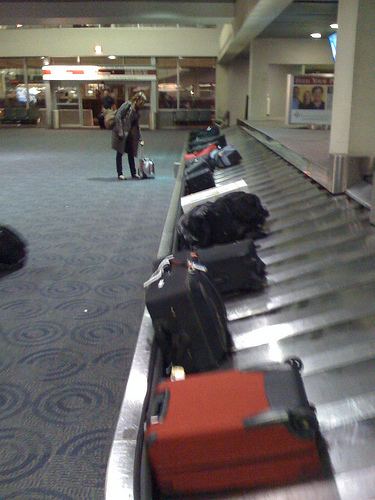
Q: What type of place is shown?
A: It is an airport.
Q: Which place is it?
A: It is an airport.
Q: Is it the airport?
A: Yes, it is the airport.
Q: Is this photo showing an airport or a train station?
A: It is showing an airport.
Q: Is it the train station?
A: No, it is the airport.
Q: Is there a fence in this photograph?
A: No, there are no fences.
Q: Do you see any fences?
A: No, there are no fences.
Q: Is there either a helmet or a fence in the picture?
A: No, there are no fences or helmets.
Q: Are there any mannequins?
A: No, there are no mannequins.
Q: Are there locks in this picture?
A: No, there are no locks.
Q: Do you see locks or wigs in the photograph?
A: No, there are no locks or wigs.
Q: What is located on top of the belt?
A: The luggage is on top of the belt.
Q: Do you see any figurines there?
A: No, there are no figurines.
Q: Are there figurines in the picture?
A: No, there are no figurines.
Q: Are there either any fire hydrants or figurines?
A: No, there are no figurines or fire hydrants.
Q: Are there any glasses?
A: No, there are no glasses.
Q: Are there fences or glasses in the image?
A: No, there are no glasses or fences.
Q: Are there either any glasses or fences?
A: No, there are no glasses or fences.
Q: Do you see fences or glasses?
A: No, there are no glasses or fences.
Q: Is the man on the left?
A: Yes, the man is on the left of the image.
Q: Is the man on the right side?
A: No, the man is on the left of the image.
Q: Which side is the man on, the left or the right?
A: The man is on the left of the image.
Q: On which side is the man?
A: The man is on the left of the image.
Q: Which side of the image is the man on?
A: The man is on the left of the image.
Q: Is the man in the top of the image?
A: Yes, the man is in the top of the image.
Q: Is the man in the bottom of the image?
A: No, the man is in the top of the image.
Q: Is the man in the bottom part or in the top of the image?
A: The man is in the top of the image.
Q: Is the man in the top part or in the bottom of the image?
A: The man is in the top of the image.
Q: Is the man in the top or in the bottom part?
A: The man is in the top of the image.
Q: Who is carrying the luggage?
A: The man is carrying the luggage.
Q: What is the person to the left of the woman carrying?
A: The man is carrying luggage.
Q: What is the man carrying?
A: The man is carrying luggage.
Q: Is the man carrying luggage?
A: Yes, the man is carrying luggage.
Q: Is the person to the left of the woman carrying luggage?
A: Yes, the man is carrying luggage.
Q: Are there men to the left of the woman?
A: Yes, there is a man to the left of the woman.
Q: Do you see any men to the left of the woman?
A: Yes, there is a man to the left of the woman.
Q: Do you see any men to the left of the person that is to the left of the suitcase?
A: Yes, there is a man to the left of the woman.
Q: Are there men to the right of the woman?
A: No, the man is to the left of the woman.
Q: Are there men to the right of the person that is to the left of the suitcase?
A: No, the man is to the left of the woman.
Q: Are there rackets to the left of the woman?
A: No, there is a man to the left of the woman.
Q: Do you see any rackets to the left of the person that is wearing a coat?
A: No, there is a man to the left of the woman.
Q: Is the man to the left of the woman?
A: Yes, the man is to the left of the woman.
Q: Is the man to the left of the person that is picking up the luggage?
A: Yes, the man is to the left of the woman.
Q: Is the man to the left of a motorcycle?
A: No, the man is to the left of the woman.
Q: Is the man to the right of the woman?
A: No, the man is to the left of the woman.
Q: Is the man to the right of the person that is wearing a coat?
A: No, the man is to the left of the woman.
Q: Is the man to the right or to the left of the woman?
A: The man is to the left of the woman.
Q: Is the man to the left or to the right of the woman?
A: The man is to the left of the woman.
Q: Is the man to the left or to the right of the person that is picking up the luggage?
A: The man is to the left of the woman.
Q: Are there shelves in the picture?
A: No, there are no shelves.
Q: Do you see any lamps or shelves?
A: No, there are no shelves or lamps.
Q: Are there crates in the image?
A: No, there are no crates.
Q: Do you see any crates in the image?
A: No, there are no crates.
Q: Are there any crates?
A: No, there are no crates.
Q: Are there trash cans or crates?
A: No, there are no crates or trash cans.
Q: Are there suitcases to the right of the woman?
A: Yes, there is a suitcase to the right of the woman.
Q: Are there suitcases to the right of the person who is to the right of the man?
A: Yes, there is a suitcase to the right of the woman.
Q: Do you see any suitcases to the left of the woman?
A: No, the suitcase is to the right of the woman.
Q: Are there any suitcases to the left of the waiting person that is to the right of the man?
A: No, the suitcase is to the right of the woman.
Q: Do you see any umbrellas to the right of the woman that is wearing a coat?
A: No, there is a suitcase to the right of the woman.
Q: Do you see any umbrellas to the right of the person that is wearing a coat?
A: No, there is a suitcase to the right of the woman.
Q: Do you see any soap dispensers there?
A: No, there are no soap dispensers.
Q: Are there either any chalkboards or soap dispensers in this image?
A: No, there are no soap dispensers or chalkboards.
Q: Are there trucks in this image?
A: No, there are no trucks.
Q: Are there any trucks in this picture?
A: No, there are no trucks.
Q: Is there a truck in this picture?
A: No, there are no trucks.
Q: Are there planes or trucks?
A: No, there are no trucks or planes.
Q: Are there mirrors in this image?
A: No, there are no mirrors.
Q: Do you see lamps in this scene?
A: No, there are no lamps.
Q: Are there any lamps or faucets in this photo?
A: No, there are no lamps or faucets.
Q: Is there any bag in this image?
A: Yes, there is a bag.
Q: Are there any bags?
A: Yes, there is a bag.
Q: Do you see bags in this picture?
A: Yes, there is a bag.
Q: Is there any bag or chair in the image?
A: Yes, there is a bag.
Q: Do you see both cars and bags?
A: No, there is a bag but no cars.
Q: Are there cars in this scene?
A: No, there are no cars.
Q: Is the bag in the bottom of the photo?
A: Yes, the bag is in the bottom of the image.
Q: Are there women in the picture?
A: Yes, there is a woman.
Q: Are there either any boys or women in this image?
A: Yes, there is a woman.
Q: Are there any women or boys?
A: Yes, there is a woman.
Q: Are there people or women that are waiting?
A: Yes, the woman is waiting.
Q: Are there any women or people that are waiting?
A: Yes, the woman is waiting.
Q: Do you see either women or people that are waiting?
A: Yes, the woman is waiting.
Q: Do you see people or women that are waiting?
A: Yes, the woman is waiting.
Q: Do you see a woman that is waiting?
A: Yes, there is a woman that is waiting.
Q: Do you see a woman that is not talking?
A: Yes, there is a woman that is waiting .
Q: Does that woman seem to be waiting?
A: Yes, the woman is waiting.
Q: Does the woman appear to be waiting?
A: Yes, the woman is waiting.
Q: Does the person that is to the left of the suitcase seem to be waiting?
A: Yes, the woman is waiting.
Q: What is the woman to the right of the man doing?
A: The woman is waiting.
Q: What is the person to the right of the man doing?
A: The woman is waiting.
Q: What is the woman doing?
A: The woman is waiting.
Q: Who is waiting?
A: The woman is waiting.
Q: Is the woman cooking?
A: No, the woman is waiting.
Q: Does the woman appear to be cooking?
A: No, the woman is waiting.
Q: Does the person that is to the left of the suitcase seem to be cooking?
A: No, the woman is waiting.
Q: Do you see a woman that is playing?
A: No, there is a woman but she is waiting.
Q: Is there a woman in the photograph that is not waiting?
A: No, there is a woman but she is waiting.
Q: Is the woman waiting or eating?
A: The woman is waiting.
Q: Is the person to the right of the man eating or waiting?
A: The woman is waiting.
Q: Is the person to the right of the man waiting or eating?
A: The woman is waiting.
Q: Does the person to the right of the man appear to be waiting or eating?
A: The woman is waiting.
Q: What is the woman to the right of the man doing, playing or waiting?
A: The woman is waiting.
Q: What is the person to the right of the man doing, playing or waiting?
A: The woman is waiting.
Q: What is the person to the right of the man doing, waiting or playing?
A: The woman is waiting.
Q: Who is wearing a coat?
A: The woman is wearing a coat.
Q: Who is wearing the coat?
A: The woman is wearing a coat.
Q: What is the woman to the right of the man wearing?
A: The woman is wearing a coat.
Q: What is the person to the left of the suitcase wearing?
A: The woman is wearing a coat.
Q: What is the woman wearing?
A: The woman is wearing a coat.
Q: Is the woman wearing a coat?
A: Yes, the woman is wearing a coat.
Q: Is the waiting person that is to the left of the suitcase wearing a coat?
A: Yes, the woman is wearing a coat.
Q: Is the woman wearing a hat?
A: No, the woman is wearing a coat.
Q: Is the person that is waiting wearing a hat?
A: No, the woman is wearing a coat.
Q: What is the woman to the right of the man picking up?
A: The woman is picking up the luggage.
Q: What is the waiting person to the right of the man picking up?
A: The woman is picking up the luggage.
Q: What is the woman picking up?
A: The woman is picking up the luggage.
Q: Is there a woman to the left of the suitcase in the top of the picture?
A: Yes, there is a woman to the left of the suitcase.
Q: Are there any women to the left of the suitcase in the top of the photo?
A: Yes, there is a woman to the left of the suitcase.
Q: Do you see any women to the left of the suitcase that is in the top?
A: Yes, there is a woman to the left of the suitcase.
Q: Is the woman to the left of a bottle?
A: No, the woman is to the left of the suitcase.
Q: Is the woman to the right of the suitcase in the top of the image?
A: No, the woman is to the left of the suitcase.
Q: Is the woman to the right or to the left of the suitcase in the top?
A: The woman is to the left of the suitcase.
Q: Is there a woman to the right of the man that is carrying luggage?
A: Yes, there is a woman to the right of the man.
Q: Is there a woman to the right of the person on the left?
A: Yes, there is a woman to the right of the man.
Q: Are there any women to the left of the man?
A: No, the woman is to the right of the man.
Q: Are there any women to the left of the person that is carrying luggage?
A: No, the woman is to the right of the man.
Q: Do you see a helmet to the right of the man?
A: No, there is a woman to the right of the man.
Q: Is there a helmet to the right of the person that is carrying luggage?
A: No, there is a woman to the right of the man.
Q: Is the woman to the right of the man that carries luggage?
A: Yes, the woman is to the right of the man.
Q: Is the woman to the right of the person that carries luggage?
A: Yes, the woman is to the right of the man.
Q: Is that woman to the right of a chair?
A: No, the woman is to the right of the man.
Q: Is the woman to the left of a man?
A: No, the woman is to the right of a man.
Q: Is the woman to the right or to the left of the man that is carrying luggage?
A: The woman is to the right of the man.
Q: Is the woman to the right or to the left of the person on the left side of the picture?
A: The woman is to the right of the man.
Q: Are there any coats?
A: Yes, there is a coat.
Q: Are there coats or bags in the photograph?
A: Yes, there is a coat.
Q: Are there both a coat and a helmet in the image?
A: No, there is a coat but no helmets.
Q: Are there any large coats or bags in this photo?
A: Yes, there is a large coat.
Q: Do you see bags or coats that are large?
A: Yes, the coat is large.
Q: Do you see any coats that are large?
A: Yes, there is a large coat.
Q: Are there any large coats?
A: Yes, there is a large coat.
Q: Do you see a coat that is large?
A: Yes, there is a coat that is large.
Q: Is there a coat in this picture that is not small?
A: Yes, there is a large coat.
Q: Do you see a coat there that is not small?
A: Yes, there is a large coat.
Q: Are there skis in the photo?
A: No, there are no skis.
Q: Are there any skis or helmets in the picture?
A: No, there are no skis or helmets.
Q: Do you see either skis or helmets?
A: No, there are no skis or helmets.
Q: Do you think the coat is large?
A: Yes, the coat is large.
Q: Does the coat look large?
A: Yes, the coat is large.